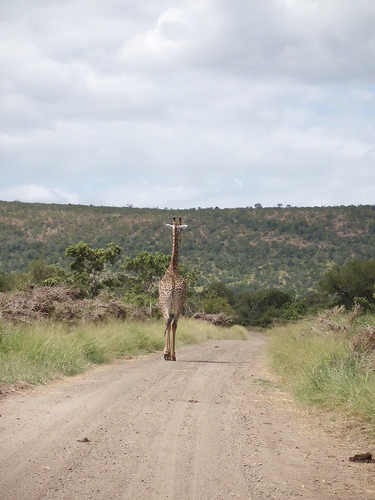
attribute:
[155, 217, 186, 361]
giraffe — large, walking, skinny, elegant, tall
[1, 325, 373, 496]
road — dirt, brown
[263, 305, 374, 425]
field — grass, lush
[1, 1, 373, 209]
sky — gray, cloudy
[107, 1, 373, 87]
cloud — gray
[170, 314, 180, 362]
leg — long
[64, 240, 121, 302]
trees — green